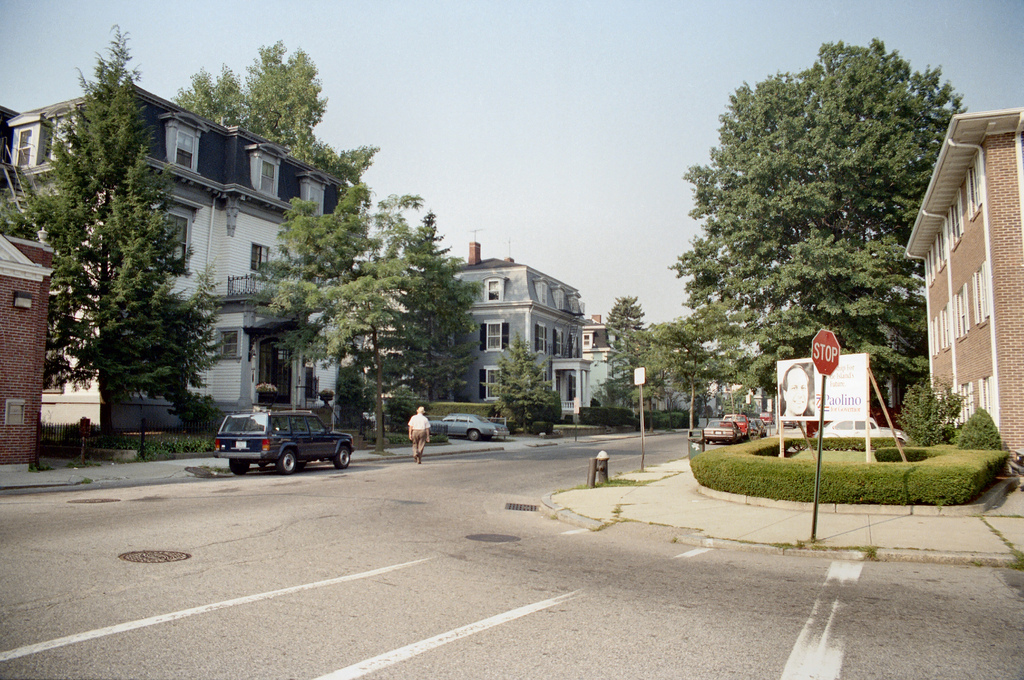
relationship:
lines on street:
[760, 551, 903, 662] [27, 485, 929, 671]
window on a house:
[224, 251, 276, 271] [129, 106, 352, 370]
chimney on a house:
[462, 227, 488, 256] [451, 210, 573, 364]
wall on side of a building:
[0, 277, 44, 453] [0, 169, 93, 483]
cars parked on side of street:
[695, 408, 773, 435] [1, 423, 708, 637]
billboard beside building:
[774, 353, 872, 421] [901, 102, 1022, 463]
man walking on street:
[408, 406, 430, 464] [6, 408, 1018, 676]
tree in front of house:
[261, 175, 432, 424] [7, 85, 362, 453]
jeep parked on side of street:
[213, 410, 355, 475] [4, 435, 1020, 675]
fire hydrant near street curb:
[594, 448, 610, 494] [539, 463, 1023, 572]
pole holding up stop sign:
[809, 374, 831, 537] [805, 329, 844, 377]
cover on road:
[118, 550, 192, 563] [0, 430, 1024, 680]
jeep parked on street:
[206, 404, 353, 476] [6, 408, 1018, 676]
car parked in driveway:
[429, 413, 511, 441] [394, 408, 548, 460]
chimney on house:
[468, 241, 482, 265] [444, 261, 583, 406]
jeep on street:
[213, 410, 355, 475] [23, 338, 1022, 678]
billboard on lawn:
[771, 351, 871, 442] [737, 443, 921, 467]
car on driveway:
[423, 411, 503, 440] [434, 428, 515, 450]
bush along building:
[955, 405, 1007, 451] [901, 102, 1022, 463]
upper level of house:
[9, 81, 349, 216] [7, 85, 362, 453]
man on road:
[406, 404, 433, 463] [9, 430, 1014, 673]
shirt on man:
[408, 413, 430, 431] [406, 404, 433, 463]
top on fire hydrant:
[596, 450, 607, 463] [588, 450, 610, 487]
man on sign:
[780, 361, 807, 418] [769, 357, 906, 463]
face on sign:
[782, 368, 809, 412] [769, 357, 906, 463]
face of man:
[782, 368, 809, 412] [780, 361, 807, 418]